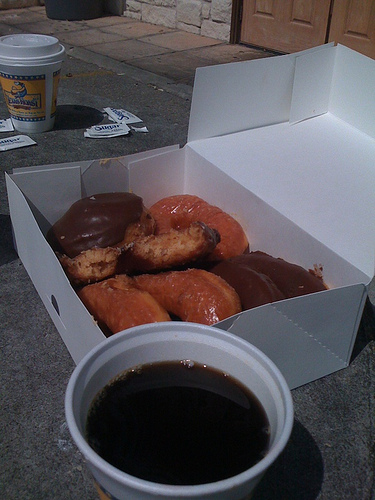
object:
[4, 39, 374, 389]
box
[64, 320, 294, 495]
cup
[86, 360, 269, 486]
coffee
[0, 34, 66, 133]
cup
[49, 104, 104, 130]
shadow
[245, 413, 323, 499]
shadow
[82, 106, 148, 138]
packs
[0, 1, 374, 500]
floor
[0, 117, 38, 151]
packs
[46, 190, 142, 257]
chocolate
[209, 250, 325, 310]
chocolate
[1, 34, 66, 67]
lid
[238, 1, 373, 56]
doors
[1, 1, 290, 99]
walk way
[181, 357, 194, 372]
bubble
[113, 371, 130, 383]
bubble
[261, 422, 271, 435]
bubble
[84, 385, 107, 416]
bubble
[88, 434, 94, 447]
bubble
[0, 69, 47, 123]
design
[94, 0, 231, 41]
wall